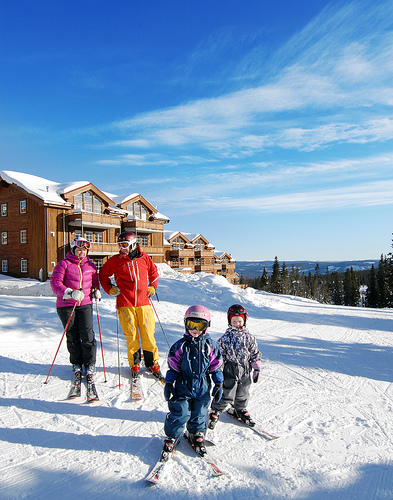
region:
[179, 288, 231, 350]
the head of a child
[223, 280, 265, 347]
the head of a boy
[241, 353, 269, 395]
the hand of a boy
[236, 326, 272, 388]
the arm of a boy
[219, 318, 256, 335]
the eyes of a boy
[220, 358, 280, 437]
the leg of a boy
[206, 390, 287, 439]
a boy wearing skis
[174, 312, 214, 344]
a kid wearing goggles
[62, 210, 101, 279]
the head of a woman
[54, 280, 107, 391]
the legs of a woman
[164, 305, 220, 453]
Person wearing blue pants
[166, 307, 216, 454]
Person wearing blue jacket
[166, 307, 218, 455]
Person wearing pink helmet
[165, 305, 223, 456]
Person wearing black boots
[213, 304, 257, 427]
Person wearing black boots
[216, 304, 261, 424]
Person wearing gray pants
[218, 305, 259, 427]
Person wearing gray jacket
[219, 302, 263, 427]
Person wearing red helmet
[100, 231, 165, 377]
Person wearing yellow pants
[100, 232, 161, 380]
Person wearing red jacket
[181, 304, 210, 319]
the helmet is pink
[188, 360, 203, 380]
the suit is blue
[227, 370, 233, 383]
the pants are gray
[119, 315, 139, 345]
the pants are yellow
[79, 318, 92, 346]
the pants are black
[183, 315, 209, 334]
she is wearing goggles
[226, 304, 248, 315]
the goggles are on the helmet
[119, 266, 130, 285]
the jacket is red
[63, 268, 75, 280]
the coat is pink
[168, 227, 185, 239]
the snow is on the roof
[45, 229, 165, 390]
Two adults on skis.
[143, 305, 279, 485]
Two children on skis.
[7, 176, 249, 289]
Brown buildings in background.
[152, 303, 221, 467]
Child in blue and purple snowsuit.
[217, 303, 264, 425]
Child in grey and white snowsuit.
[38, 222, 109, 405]
Woman wearing in pink coat.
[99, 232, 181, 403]
Skier wearing red coat.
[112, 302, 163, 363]
Yellow and black snowpants.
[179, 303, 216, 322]
Pink ski helmet worn by child.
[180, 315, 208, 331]
Black and yellow ski goggles.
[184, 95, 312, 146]
clouds in the sky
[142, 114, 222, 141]
the clouds are white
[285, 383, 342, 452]
the snow is white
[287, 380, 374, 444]
the white snow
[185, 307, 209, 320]
child is wearing a helmet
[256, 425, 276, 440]
the ski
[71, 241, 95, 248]
ski goggles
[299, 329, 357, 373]
the shadow on the snow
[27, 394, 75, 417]
a reflection on the snow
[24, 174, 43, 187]
white snow on the roof